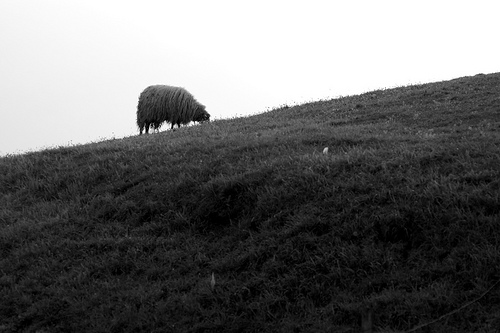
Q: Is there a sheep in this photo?
A: Yes, there is a sheep.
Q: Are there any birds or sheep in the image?
A: Yes, there is a sheep.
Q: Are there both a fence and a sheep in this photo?
A: No, there is a sheep but no fences.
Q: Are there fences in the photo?
A: No, there are no fences.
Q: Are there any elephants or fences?
A: No, there are no fences or elephants.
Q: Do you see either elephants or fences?
A: No, there are no fences or elephants.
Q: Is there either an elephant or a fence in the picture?
A: No, there are no fences or elephants.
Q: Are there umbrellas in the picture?
A: No, there are no umbrellas.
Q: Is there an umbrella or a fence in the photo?
A: No, there are no umbrellas or fences.